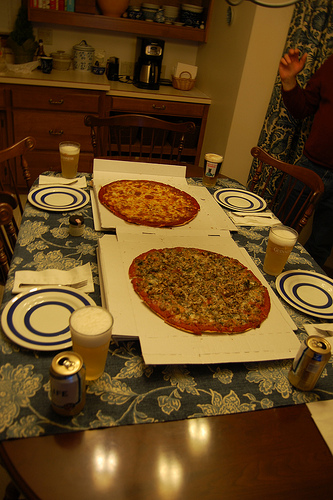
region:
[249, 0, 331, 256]
a curtain is hanging behind the guy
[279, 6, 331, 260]
a person is standing in front of the curtain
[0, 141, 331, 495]
dinner is served on the table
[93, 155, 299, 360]
two pizzas kept besides each other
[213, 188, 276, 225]
a fork on a tissue paper kept beside the plate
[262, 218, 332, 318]
a glass of beer near the plate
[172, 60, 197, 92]
a basked with a tissue paper in it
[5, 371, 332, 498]
the reflection of light lamps near the table cloth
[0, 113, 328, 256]
wooden chairs arranged around the table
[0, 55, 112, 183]
a table with closed drawers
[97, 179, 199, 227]
the whole pizza on the box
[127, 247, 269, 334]
the whole pizza on the box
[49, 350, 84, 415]
the can on the table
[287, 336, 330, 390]
the can on the table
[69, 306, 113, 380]
the cup filled with beer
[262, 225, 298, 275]
the cup filled with beer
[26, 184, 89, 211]
the empty plate on the table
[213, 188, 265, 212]
the empty plate on the table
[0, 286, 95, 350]
the empty plate on the table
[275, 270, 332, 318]
the empty plate on the table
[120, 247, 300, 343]
the pizza is big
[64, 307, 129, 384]
the beer is frofthy.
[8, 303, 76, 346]
the plate has a design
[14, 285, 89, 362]
the plate is blue and white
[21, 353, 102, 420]
the beer can is shiny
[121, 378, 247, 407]
the table cloth has a design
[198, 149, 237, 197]
the glass has a design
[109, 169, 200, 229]
the pizza has cheese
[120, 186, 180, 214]
the pizza has pepperoni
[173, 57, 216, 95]
the napkins are in a basket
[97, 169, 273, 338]
Pizzas on a table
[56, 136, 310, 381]
Glasses of beer on a table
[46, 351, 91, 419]
Can on a table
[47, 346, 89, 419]
Can of beer on a table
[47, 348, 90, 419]
Open can on a table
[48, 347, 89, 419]
Open can of beer on a table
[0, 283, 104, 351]
Plate on a table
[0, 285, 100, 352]
Round plate on a table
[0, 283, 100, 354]
White and blue plate on a table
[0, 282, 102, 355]
Round white and blue plate on a table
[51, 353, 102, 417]
gold can on table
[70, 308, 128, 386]
clear glass on table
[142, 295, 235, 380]
white box on table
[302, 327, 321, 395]
gold can on table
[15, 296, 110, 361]
white plate on table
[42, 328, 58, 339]
blue line on plate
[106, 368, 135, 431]
blue flower on cloth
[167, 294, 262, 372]
pizza on white box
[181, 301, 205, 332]
brown crust on pizza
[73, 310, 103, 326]
white foam on drink